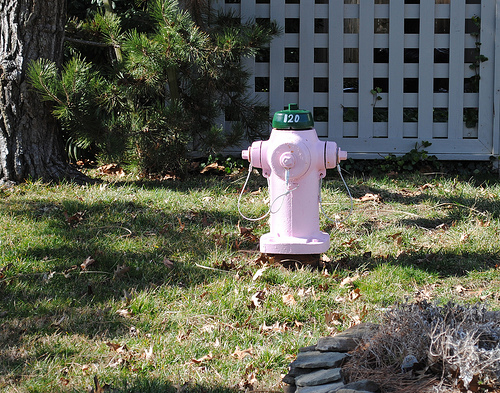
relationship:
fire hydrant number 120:
[236, 99, 354, 267] [281, 110, 303, 126]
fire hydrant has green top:
[236, 99, 354, 267] [269, 101, 319, 132]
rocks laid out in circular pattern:
[282, 304, 370, 383] [285, 302, 497, 383]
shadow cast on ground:
[362, 166, 494, 230] [4, 165, 498, 383]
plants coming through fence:
[458, 11, 492, 70] [207, 6, 499, 169]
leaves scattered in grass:
[69, 253, 362, 350] [4, 165, 498, 383]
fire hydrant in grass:
[236, 99, 354, 267] [4, 165, 498, 383]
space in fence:
[371, 46, 388, 67] [207, 6, 499, 169]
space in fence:
[312, 17, 329, 33] [207, 6, 499, 169]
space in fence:
[432, 77, 450, 90] [207, 6, 499, 169]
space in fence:
[402, 17, 422, 32] [207, 6, 499, 169]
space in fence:
[341, 105, 358, 123] [207, 6, 499, 169]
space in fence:
[403, 108, 419, 121] [207, 6, 499, 169]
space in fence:
[284, 74, 299, 92] [207, 6, 499, 169]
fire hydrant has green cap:
[236, 99, 354, 267] [269, 101, 319, 132]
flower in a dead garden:
[353, 290, 490, 380] [285, 302, 497, 383]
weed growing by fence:
[463, 48, 490, 71] [207, 6, 499, 169]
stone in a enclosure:
[282, 304, 370, 383] [285, 302, 497, 383]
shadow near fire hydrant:
[8, 184, 224, 344] [236, 99, 354, 267]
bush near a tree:
[24, 1, 273, 190] [4, 2, 79, 180]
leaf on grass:
[77, 251, 98, 275] [4, 165, 498, 383]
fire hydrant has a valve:
[236, 99, 354, 267] [267, 135, 313, 187]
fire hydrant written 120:
[236, 99, 354, 267] [281, 110, 303, 126]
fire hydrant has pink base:
[236, 99, 354, 267] [252, 233, 336, 258]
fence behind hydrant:
[207, 6, 499, 169] [236, 99, 354, 267]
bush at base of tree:
[24, 1, 273, 190] [4, 2, 79, 180]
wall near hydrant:
[236, 99, 354, 267] [236, 99, 354, 267]